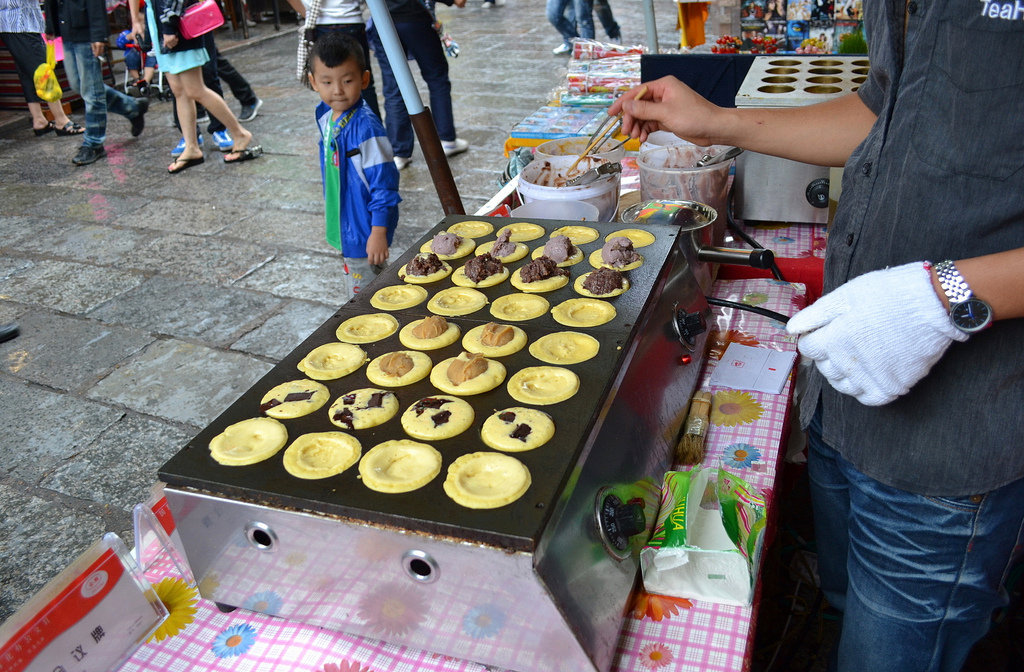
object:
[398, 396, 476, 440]
food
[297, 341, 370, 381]
food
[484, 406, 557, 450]
food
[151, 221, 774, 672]
griddle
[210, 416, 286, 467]
food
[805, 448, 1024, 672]
jeans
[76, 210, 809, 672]
table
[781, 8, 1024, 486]
shirt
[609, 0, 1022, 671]
man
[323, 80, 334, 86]
eyes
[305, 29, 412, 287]
boy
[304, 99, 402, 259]
jacket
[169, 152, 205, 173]
sandals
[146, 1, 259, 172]
lady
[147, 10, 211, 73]
skirt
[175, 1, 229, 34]
purse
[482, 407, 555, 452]
cookie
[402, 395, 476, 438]
cookie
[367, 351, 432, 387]
cookie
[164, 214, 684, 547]
grill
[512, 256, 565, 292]
cookie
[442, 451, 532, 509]
cookie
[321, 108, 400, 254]
shirt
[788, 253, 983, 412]
hand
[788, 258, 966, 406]
glove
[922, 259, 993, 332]
wrist watch